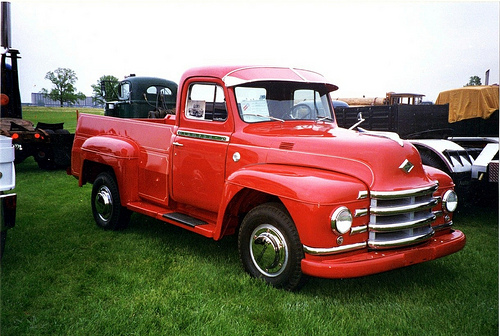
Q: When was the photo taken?
A: Daytime.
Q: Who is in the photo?
A: Nobody.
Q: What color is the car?
A: Red.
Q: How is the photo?
A: Clear.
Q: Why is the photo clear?
A: Its during the day.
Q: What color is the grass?
A: Green.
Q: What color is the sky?
A: White.